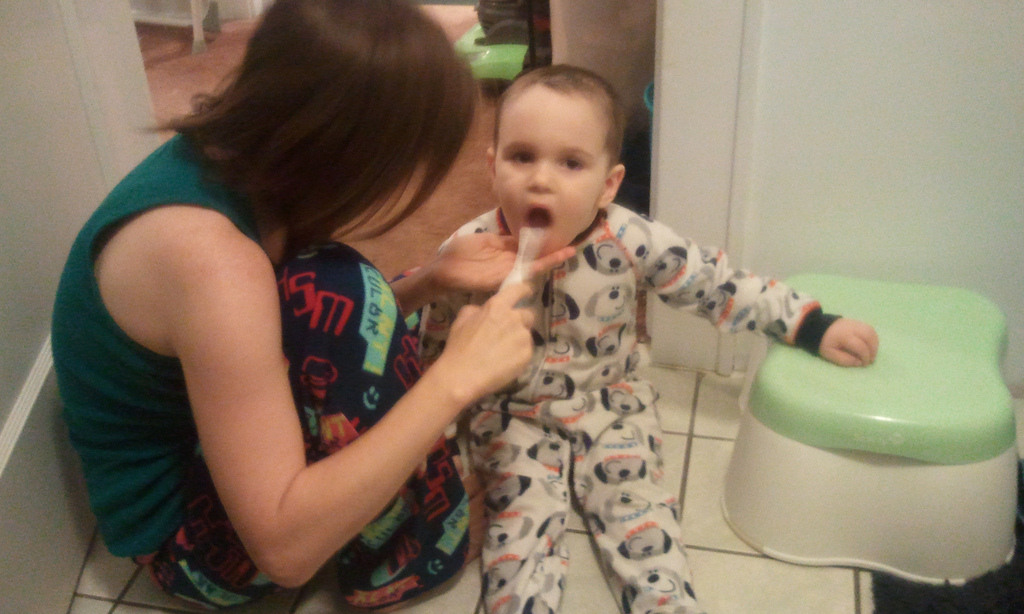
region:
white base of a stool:
[698, 411, 1022, 599]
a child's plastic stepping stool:
[708, 258, 1021, 587]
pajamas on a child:
[407, 203, 837, 606]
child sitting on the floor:
[411, 59, 884, 611]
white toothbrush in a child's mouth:
[483, 217, 542, 323]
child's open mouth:
[514, 198, 560, 240]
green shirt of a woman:
[40, 119, 279, 579]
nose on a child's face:
[525, 164, 555, 196]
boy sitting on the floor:
[479, 64, 882, 606]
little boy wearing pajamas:
[454, 9, 882, 610]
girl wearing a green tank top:
[41, 1, 501, 611]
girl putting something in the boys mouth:
[49, 6, 882, 611]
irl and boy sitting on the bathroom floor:
[56, 3, 869, 607]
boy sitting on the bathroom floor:
[474, 4, 871, 611]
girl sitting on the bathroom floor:
[46, 6, 492, 611]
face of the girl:
[214, 34, 475, 254]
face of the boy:
[486, 42, 690, 295]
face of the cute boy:
[448, 29, 684, 324]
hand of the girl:
[340, 347, 672, 560]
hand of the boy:
[780, 255, 911, 451]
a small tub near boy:
[739, 357, 914, 493]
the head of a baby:
[465, 48, 628, 246]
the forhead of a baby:
[497, 86, 593, 141]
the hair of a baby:
[506, 54, 605, 103]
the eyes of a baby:
[500, 133, 602, 182]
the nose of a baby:
[520, 168, 569, 200]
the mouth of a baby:
[523, 198, 561, 233]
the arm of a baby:
[614, 209, 889, 399]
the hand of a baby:
[816, 315, 883, 370]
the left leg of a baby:
[547, 446, 707, 606]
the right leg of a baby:
[473, 429, 563, 607]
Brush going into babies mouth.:
[497, 206, 543, 317]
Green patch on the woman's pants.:
[339, 259, 415, 384]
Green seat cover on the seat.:
[757, 253, 979, 454]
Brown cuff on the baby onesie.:
[789, 300, 835, 361]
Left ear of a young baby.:
[602, 162, 622, 200]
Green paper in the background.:
[462, 40, 523, 75]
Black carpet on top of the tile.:
[868, 563, 941, 609]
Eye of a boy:
[558, 148, 584, 174]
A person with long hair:
[40, 16, 537, 606]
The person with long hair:
[33, 11, 572, 597]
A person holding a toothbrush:
[494, 216, 570, 296]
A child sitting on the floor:
[425, 69, 884, 608]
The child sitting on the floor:
[432, 57, 837, 611]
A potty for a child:
[710, 265, 1021, 608]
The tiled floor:
[110, 319, 891, 601]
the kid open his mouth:
[437, 44, 885, 599]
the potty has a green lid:
[702, 245, 1021, 594]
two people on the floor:
[4, 13, 856, 609]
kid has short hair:
[472, 50, 639, 278]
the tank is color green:
[35, 124, 263, 574]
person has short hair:
[76, 3, 491, 365]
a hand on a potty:
[758, 302, 898, 391]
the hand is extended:
[624, 206, 885, 375]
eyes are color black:
[495, 138, 596, 182]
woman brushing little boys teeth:
[39, 0, 586, 611]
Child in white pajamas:
[417, 73, 869, 589]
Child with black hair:
[408, 62, 889, 610]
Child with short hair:
[432, 63, 885, 601]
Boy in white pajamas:
[404, 53, 882, 603]